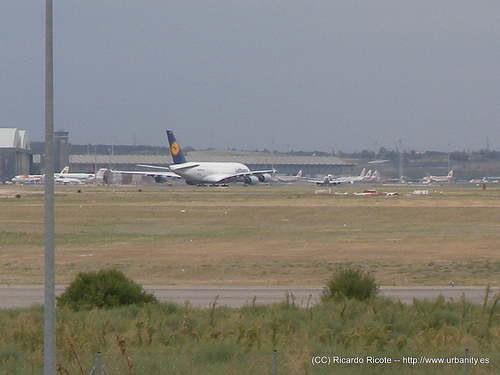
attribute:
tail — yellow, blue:
[164, 129, 187, 166]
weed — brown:
[115, 334, 130, 354]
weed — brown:
[122, 354, 133, 373]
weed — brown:
[62, 332, 85, 372]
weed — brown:
[52, 360, 69, 372]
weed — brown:
[99, 312, 111, 343]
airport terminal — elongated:
[33, 148, 358, 178]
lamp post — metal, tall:
[41, 0, 58, 372]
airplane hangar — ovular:
[2, 126, 22, 182]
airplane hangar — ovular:
[17, 128, 34, 176]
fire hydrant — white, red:
[481, 180, 484, 188]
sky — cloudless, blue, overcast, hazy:
[2, 1, 483, 153]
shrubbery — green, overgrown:
[53, 264, 160, 308]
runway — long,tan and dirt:
[91, 270, 494, 287]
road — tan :
[138, 176, 467, 314]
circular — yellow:
[153, 99, 213, 222]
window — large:
[18, 148, 106, 243]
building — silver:
[52, 150, 417, 286]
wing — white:
[83, 124, 188, 231]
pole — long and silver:
[42, 84, 72, 338]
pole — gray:
[32, 195, 79, 375]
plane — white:
[104, 124, 306, 225]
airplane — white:
[154, 139, 289, 173]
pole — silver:
[31, 74, 94, 347]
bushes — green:
[74, 290, 498, 375]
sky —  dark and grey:
[43, 51, 393, 140]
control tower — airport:
[50, 129, 66, 178]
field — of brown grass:
[10, 193, 462, 283]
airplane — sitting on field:
[139, 130, 279, 190]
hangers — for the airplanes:
[0, 128, 33, 181]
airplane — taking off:
[422, 163, 455, 189]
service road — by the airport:
[4, 279, 481, 309]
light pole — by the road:
[38, 3, 60, 373]